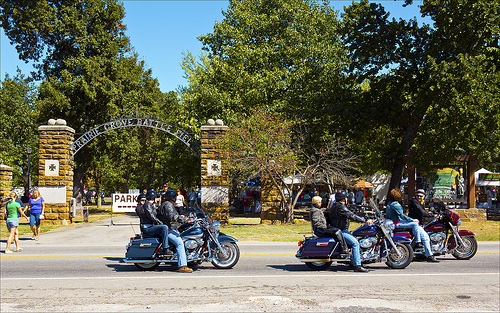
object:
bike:
[291, 198, 417, 271]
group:
[112, 185, 480, 276]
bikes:
[117, 193, 242, 271]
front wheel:
[382, 240, 417, 270]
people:
[322, 187, 374, 275]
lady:
[306, 194, 354, 258]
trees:
[0, 0, 202, 190]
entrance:
[37, 117, 228, 229]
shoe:
[175, 264, 195, 274]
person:
[153, 185, 200, 275]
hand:
[183, 214, 198, 225]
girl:
[21, 188, 48, 242]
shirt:
[1, 201, 22, 221]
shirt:
[28, 197, 45, 214]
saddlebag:
[313, 227, 341, 243]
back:
[294, 221, 343, 269]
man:
[325, 190, 374, 275]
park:
[0, 0, 500, 223]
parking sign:
[109, 192, 162, 214]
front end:
[362, 212, 417, 271]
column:
[31, 117, 77, 223]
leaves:
[455, 84, 486, 108]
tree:
[292, 0, 499, 208]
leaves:
[467, 14, 494, 33]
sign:
[65, 114, 201, 159]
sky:
[0, 0, 446, 102]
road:
[0, 246, 497, 313]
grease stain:
[293, 297, 406, 312]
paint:
[0, 248, 499, 260]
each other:
[3, 192, 32, 255]